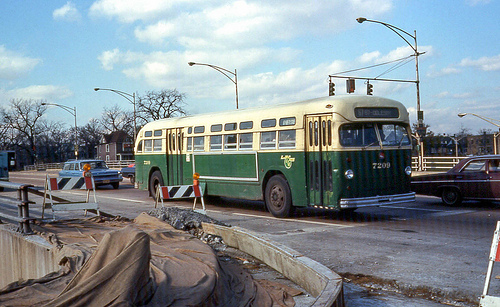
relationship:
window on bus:
[221, 122, 241, 152] [129, 83, 422, 223]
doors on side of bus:
[153, 121, 336, 213] [125, 96, 417, 207]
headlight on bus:
[402, 164, 414, 176] [131, 92, 416, 217]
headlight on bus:
[341, 166, 356, 179] [131, 92, 416, 217]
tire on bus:
[252, 172, 294, 227] [112, 91, 417, 213]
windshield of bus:
[333, 116, 427, 148] [112, 91, 417, 213]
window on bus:
[252, 121, 339, 162] [125, 96, 417, 207]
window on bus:
[260, 119, 277, 150] [125, 96, 417, 207]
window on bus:
[142, 129, 151, 149] [131, 92, 416, 217]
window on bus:
[258, 118, 275, 145] [131, 92, 416, 217]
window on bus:
[221, 121, 237, 146] [131, 92, 416, 217]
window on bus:
[207, 122, 221, 147] [131, 92, 416, 217]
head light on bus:
[342, 168, 353, 179] [131, 92, 416, 217]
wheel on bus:
[262, 171, 299, 213] [133, 94, 419, 218]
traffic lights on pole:
[327, 74, 372, 99] [320, 66, 425, 200]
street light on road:
[458, 111, 499, 125] [3, 171, 48, 186]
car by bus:
[414, 145, 499, 208] [131, 92, 416, 217]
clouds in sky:
[1, 86, 68, 105] [1, 2, 499, 142]